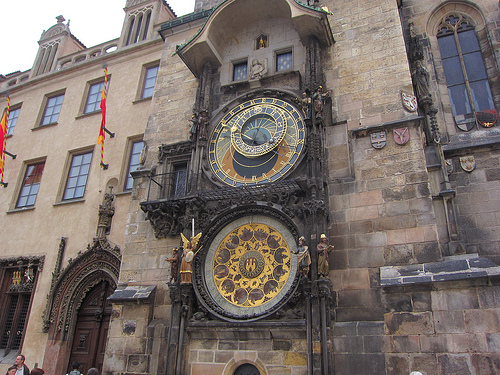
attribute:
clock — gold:
[194, 85, 318, 200]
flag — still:
[0, 95, 9, 181]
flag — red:
[1, 92, 18, 182]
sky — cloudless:
[5, 0, 195, 65]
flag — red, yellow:
[99, 69, 109, 165]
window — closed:
[130, 54, 170, 103]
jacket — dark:
[12, 367, 37, 373]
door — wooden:
[62, 278, 112, 369]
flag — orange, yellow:
[2, 90, 21, 177]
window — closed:
[273, 48, 295, 73]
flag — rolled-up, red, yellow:
[96, 67, 108, 167]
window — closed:
[440, 27, 495, 129]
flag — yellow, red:
[91, 66, 111, 166]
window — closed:
[145, 57, 168, 123]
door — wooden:
[146, 240, 284, 372]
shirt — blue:
[16, 366, 24, 373]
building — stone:
[2, 0, 497, 374]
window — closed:
[60, 148, 91, 200]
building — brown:
[102, 1, 494, 373]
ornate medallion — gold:
[210, 222, 294, 309]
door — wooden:
[62, 282, 122, 367]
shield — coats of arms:
[167, 200, 335, 327]